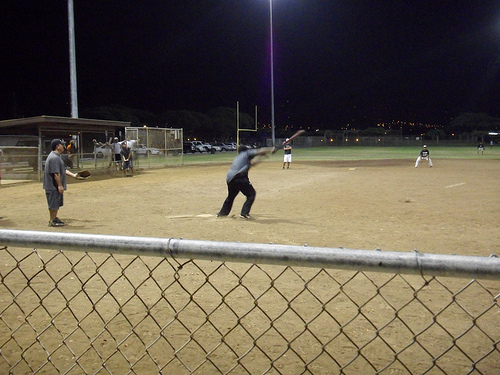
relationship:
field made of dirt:
[165, 144, 489, 258] [331, 193, 371, 228]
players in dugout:
[37, 140, 81, 207] [9, 110, 121, 161]